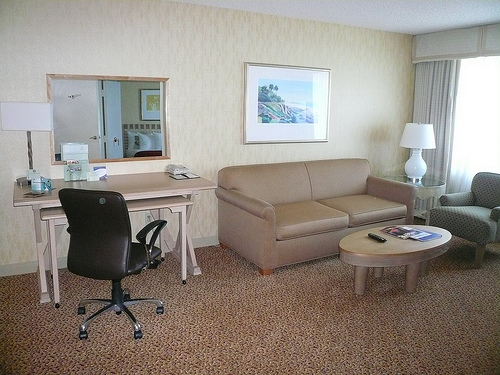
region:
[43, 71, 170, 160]
a wall mirror mounted on the wall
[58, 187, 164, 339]
a black office chair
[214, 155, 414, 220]
a brown sofa against the wall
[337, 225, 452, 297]
a wooden coffee table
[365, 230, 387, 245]
a black tv remote control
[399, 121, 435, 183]
a white table lamp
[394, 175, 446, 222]
a round corner table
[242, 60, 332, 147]
a framed picture mounted on the wall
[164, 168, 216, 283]
a light wood office desk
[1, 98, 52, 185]
a table lamp on the desk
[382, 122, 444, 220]
a white table lamp on a round table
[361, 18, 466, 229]
a lamp in the corner of a room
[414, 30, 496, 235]
a glass window with a curtain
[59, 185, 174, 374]
a swivel chair on the floor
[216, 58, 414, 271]
a picture hanging on the wall above the sofa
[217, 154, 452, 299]
a table in front of the sofa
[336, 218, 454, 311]
an oval shaped table on the floor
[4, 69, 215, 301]
a mirror on the wall is above the table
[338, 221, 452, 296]
a remote control is kept on the table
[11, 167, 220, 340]
a chair in front of the table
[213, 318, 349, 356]
grainy tan color on carpet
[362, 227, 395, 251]
black remote on table top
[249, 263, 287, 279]
small brown legs on the sofa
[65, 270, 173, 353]
shiny black wheel base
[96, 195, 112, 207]
tiny gray circle on back of chair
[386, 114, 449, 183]
white lamp on table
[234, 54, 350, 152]
white picture on wall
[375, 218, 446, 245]
books on top of table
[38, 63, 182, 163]
square mirror on wall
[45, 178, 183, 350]
large black swivel chair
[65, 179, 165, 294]
Big black chair in the room.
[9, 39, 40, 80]
Big black chair in the room.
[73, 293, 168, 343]
Casters on the bottom of a desk chair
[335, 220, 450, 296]
An oval shaped coffee table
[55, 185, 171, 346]
A desk chair on casters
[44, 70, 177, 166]
A framed mirror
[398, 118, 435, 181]
A white table lamp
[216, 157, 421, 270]
A tan leather couch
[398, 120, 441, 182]
A white lamp and lamp shade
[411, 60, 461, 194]
White curtains behind a lamp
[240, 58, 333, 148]
Framed artwork on a wall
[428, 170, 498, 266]
An accent chair